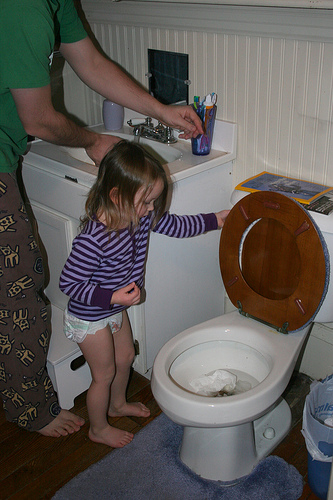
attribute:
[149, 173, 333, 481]
toilet — white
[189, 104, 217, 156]
glass — purple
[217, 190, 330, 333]
toilet seat — brown, wooden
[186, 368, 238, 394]
toilet paper — white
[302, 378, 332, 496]
wastebasket — blue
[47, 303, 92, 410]
step stool — white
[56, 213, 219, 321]
shirt — purple, striped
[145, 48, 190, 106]
mirror — small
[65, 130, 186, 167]
sink — white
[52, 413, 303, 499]
rug — blue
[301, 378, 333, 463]
trash bag — white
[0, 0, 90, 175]
shirt — green